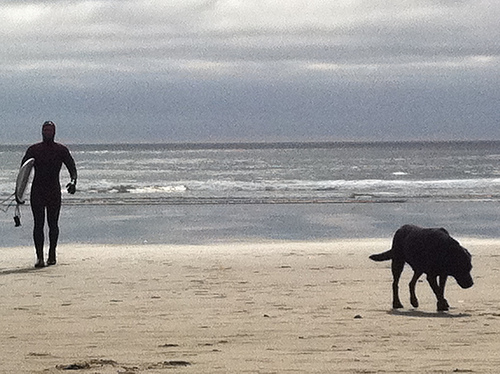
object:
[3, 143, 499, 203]
waves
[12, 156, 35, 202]
surf board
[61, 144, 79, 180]
arm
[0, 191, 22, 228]
rope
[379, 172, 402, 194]
ground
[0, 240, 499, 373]
ground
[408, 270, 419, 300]
leg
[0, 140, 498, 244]
water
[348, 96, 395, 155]
wall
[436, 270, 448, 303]
leg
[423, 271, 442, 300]
leg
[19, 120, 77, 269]
suit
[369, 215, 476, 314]
dog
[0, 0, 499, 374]
beach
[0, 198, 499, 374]
sand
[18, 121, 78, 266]
man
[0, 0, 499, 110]
clouds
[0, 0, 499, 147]
sky